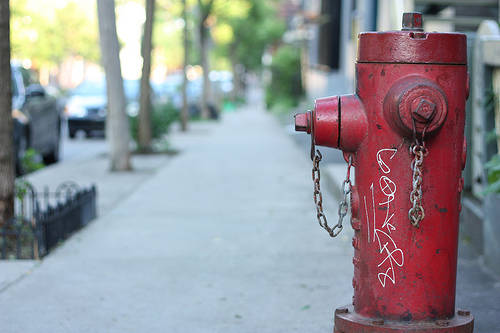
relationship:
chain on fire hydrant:
[404, 114, 431, 226] [288, 10, 475, 331]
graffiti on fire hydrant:
[361, 144, 407, 289] [293, 9, 475, 332]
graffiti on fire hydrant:
[361, 140, 404, 286] [288, 10, 475, 331]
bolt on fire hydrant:
[408, 92, 440, 124] [288, 10, 475, 331]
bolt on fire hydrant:
[456, 307, 470, 317] [288, 10, 475, 331]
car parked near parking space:
[11, 58, 63, 172] [13, 133, 114, 180]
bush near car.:
[122, 97, 182, 154] [51, 54, 143, 166]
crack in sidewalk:
[1, 259, 41, 292] [0, 89, 360, 329]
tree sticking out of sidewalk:
[92, 0, 134, 174] [0, 89, 360, 329]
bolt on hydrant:
[369, 315, 387, 328] [288, 12, 483, 331]